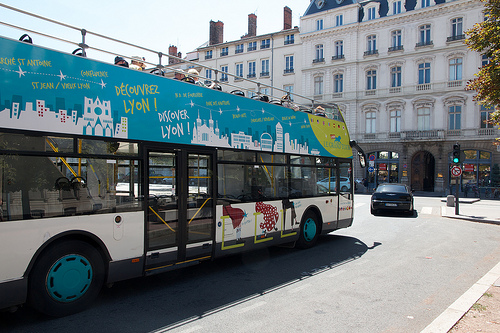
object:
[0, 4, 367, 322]
bus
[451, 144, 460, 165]
traffic light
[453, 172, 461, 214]
pole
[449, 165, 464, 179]
sign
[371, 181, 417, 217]
car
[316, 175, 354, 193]
car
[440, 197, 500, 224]
sidewalk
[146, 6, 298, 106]
buildng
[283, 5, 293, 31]
chimneys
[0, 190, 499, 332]
street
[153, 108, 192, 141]
print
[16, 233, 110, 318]
wheel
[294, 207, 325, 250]
front wheel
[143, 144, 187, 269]
door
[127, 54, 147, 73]
people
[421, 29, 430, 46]
windows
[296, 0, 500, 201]
building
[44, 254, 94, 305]
hubcap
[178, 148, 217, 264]
doors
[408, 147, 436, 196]
doorway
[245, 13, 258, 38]
chinmey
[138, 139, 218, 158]
frame